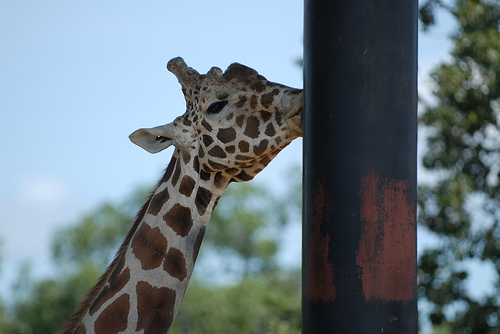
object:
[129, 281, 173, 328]
spots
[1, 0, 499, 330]
day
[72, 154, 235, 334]
neck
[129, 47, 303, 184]
head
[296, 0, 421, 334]
pole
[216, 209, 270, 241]
trees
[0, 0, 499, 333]
background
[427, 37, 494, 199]
tree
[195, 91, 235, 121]
eyes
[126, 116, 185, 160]
ear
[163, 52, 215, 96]
horn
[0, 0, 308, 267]
sky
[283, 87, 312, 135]
lips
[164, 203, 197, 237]
spot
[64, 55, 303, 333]
giraffe